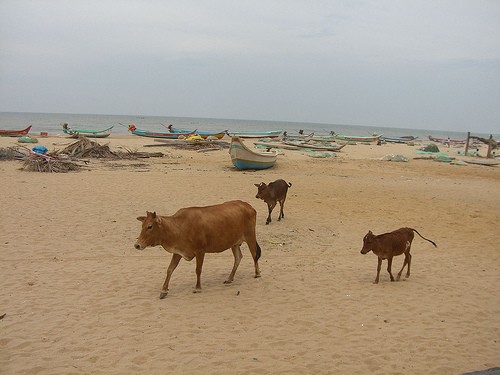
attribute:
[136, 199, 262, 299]
cow — walking, pictured, adult, brown, animal, healthy, sandy, large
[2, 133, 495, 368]
beach — sand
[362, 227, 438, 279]
calf — walking, brown, young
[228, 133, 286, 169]
boat — turquoise, blue, white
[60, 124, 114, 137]
boat — white, green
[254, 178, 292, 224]
cow — pictured, walking, brown, small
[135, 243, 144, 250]
nose — tan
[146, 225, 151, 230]
eye — dark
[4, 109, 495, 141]
water — ocean, distant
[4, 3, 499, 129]
sky — gray-blue, cloudy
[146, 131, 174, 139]
stripe — red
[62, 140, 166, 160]
tree limbs — piled